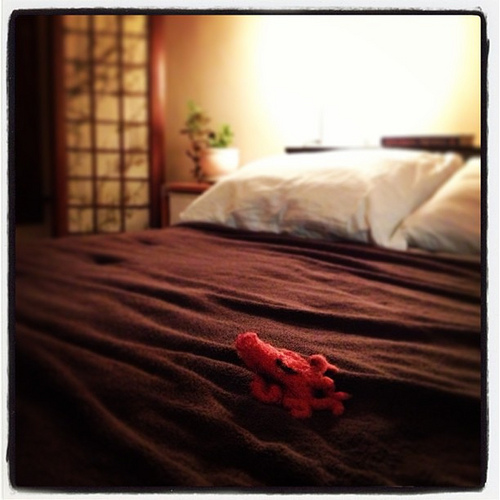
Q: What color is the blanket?
A: Maroon.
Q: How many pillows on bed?
A: Two.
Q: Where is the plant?
A: Beside the bed.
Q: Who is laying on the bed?
A: No one.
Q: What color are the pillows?
A: White.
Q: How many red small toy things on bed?
A: One.